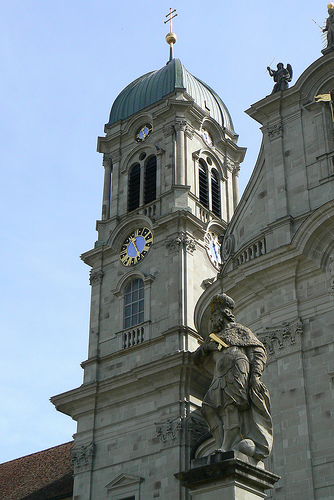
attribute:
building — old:
[49, 52, 246, 497]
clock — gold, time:
[121, 228, 155, 261]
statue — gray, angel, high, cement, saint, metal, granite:
[265, 45, 296, 92]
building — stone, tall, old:
[25, 6, 323, 481]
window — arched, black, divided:
[125, 160, 176, 201]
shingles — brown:
[156, 25, 209, 43]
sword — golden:
[258, 41, 276, 71]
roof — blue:
[111, 72, 168, 99]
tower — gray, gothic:
[316, 66, 324, 83]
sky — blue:
[9, 19, 37, 31]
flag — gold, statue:
[305, 86, 331, 110]